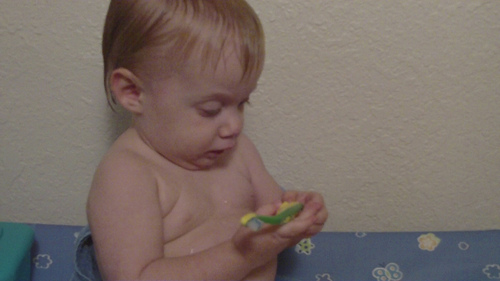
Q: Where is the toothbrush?
A: Baby's hand.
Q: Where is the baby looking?
A: Down.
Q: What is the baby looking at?
A: Toothbrush.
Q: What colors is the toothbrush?
A: Yellow and green.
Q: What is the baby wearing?
A: Nothing.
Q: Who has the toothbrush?
A: The baby.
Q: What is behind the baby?
A: Wall.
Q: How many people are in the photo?
A: One.